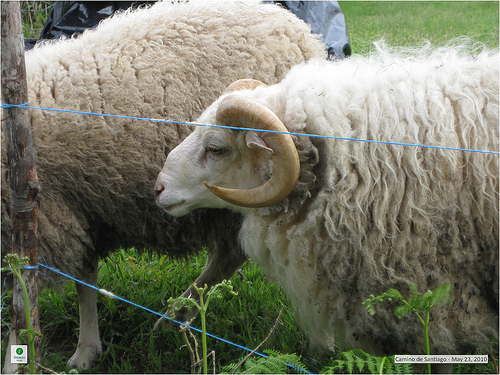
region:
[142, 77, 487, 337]
The sheep stands by the fence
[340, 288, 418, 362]
Green weed in the grass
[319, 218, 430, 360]
Dirty wool on the sheep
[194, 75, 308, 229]
Sheep has long curled horns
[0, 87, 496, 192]
Blue fence wire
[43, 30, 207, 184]
Sheep has matted hair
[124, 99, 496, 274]
The sheep is looking to the left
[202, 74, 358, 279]
The sheep has brown horns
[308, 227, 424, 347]
The sheeps fur is matted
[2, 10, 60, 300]
Wooden pole on fence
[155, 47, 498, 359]
an adult ram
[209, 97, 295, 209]
a tan ram horn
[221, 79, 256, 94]
a tan ram horn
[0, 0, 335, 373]
a large white wooly sheep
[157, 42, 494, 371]
a white wooly sheep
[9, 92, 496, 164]
a blue fence wire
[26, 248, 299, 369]
a blue fence wire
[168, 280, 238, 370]
a tall green weed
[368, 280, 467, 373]
a tall green weed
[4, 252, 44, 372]
a tall green weed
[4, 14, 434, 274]
2 sheep side by side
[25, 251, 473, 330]
green grass beside the sheep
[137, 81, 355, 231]
sheep face with horns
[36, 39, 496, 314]
2 sheep in need of shearing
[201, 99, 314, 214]
sheep curled horns on left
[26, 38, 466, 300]
2 sheep together in grass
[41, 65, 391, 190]
sheep together in grass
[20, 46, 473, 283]
2 sheep in grass together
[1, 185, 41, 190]
partial fencepost in front of sheep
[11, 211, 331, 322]
fenceline to keep sheep in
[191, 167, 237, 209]
tip of a horn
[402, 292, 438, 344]
part of a plant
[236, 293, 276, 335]
part of some grass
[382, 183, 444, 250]
part of a sheep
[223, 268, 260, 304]
part of a ground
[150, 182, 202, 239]
part of a mouth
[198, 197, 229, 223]
edge of a neck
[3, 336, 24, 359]
part of a sticker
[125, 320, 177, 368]
part of a shade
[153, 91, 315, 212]
white ram with curved horns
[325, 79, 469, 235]
white ram is fluffy and dirty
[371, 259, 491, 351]
small green weed by ram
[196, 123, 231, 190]
eye of white ram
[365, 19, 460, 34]
green grass in field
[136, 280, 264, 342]
blue rope in front of ram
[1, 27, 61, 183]
wooden pole holding blue rope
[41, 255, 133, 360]
leg of dirty white ram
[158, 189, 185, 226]
mouth of fluffy white ram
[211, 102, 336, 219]
horn of fluffy and dirty ram